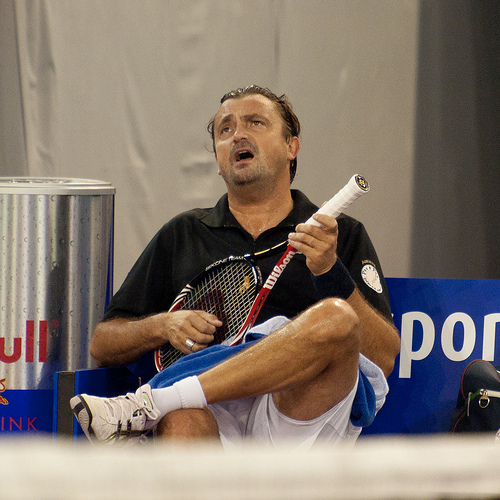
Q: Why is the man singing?
A: To be funny.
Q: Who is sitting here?
A: A tennis player.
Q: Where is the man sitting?
A: On a bench.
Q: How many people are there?
A: One.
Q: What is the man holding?
A: A tennis racket.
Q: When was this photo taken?
A: During the day.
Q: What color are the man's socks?
A: White.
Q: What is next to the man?
A: A giant can of Red Bull.